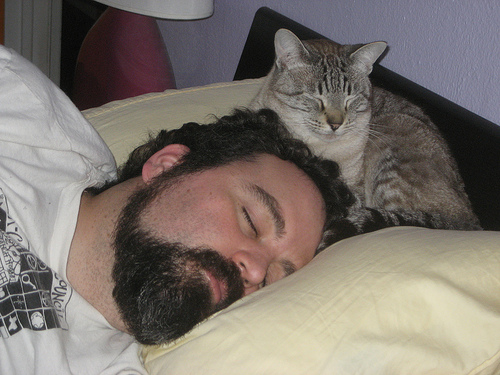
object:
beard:
[108, 176, 248, 349]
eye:
[344, 90, 364, 113]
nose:
[325, 112, 344, 132]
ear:
[273, 26, 313, 68]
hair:
[90, 100, 361, 241]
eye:
[304, 91, 326, 114]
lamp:
[62, 0, 219, 113]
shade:
[91, 0, 217, 23]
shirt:
[0, 41, 154, 375]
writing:
[0, 193, 76, 338]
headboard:
[229, 5, 500, 250]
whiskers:
[368, 136, 373, 142]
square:
[43, 308, 61, 330]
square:
[30, 311, 45, 329]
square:
[21, 252, 38, 270]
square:
[0, 229, 70, 340]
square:
[2, 310, 24, 337]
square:
[2, 294, 15, 321]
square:
[10, 294, 28, 310]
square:
[19, 270, 38, 294]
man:
[0, 45, 365, 375]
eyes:
[260, 262, 279, 288]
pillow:
[79, 74, 500, 375]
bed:
[0, 0, 500, 375]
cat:
[244, 25, 487, 257]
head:
[107, 103, 361, 351]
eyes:
[238, 204, 262, 241]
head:
[271, 27, 391, 144]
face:
[116, 152, 331, 348]